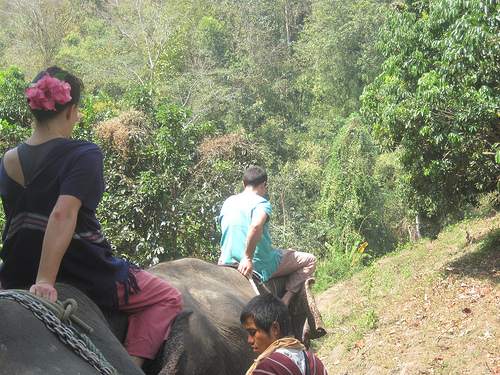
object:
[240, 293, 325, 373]
man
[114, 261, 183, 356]
pants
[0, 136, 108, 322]
woman`s back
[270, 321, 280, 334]
ear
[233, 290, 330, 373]
boy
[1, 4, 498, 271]
trees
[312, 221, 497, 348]
grass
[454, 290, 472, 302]
leaf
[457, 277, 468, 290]
leaf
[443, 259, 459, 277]
leaf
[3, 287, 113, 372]
chains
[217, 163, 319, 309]
man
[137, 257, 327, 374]
elephant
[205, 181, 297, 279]
shirt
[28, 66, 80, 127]
head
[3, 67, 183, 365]
people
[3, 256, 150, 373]
elephant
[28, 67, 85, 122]
hair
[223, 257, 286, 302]
seat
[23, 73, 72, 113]
flower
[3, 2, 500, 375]
hill